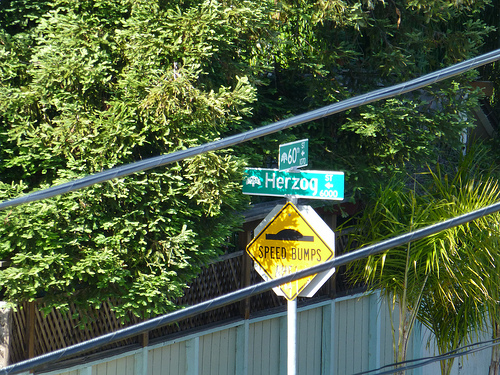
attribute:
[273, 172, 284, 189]
letter — white 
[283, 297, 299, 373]
post — white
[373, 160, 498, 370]
palmtree — in the distance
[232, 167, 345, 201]
sign — white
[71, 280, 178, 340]
fence — brown, wooden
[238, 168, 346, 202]
sign — white , Green , street, on the road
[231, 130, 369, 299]
signs — road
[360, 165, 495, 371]
palmtrees — green 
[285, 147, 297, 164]
60 — number, sign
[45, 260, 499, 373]
fencing — White 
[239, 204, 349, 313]
post — white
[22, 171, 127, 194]
pole — metal 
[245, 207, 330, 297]
diamond sign — Yellow , black 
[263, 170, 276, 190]
letter — white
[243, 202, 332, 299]
sign — square, yellow, street, on the road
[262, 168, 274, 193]
letter — white 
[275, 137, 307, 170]
sign — street, on the road